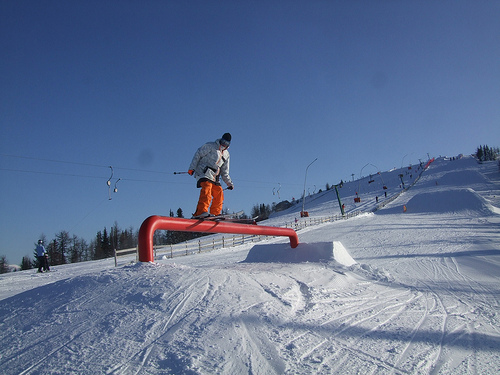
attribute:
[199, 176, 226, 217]
pants — orange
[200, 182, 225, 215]
pants — orange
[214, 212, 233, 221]
ski — white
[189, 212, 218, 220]
ski — white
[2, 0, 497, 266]
sky — cloudless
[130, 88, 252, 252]
person — skiing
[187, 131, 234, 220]
person — skiing, athletic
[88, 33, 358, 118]
sky — blue, clear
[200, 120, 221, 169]
coat — grey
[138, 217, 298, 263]
pipe — red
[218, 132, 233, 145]
hat — black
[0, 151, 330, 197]
wires — black